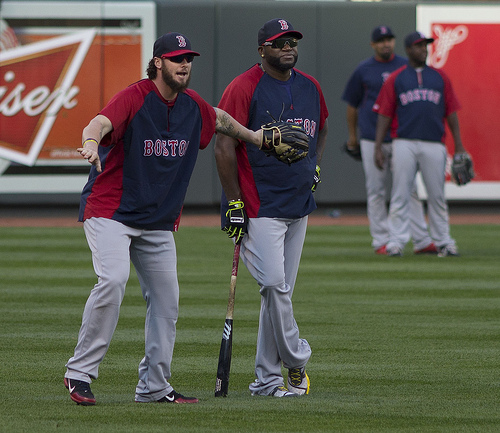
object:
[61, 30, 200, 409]
man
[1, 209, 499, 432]
field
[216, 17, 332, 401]
man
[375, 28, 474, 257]
man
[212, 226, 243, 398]
bat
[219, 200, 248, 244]
gloves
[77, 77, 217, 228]
jersey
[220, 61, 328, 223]
jersey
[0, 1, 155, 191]
sign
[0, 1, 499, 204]
wall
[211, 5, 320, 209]
panels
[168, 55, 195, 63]
sunglasses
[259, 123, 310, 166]
mitt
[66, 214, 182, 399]
pants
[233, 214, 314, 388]
pants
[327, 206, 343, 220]
baseball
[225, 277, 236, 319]
wood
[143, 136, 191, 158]
boston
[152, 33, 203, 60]
baseball hat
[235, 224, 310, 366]
legs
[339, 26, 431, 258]
player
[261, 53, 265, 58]
earring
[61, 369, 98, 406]
shoes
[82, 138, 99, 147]
bracelet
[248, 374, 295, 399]
sneakers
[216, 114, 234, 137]
tattoo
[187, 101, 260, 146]
arm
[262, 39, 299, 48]
sunglasses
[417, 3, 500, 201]
sign